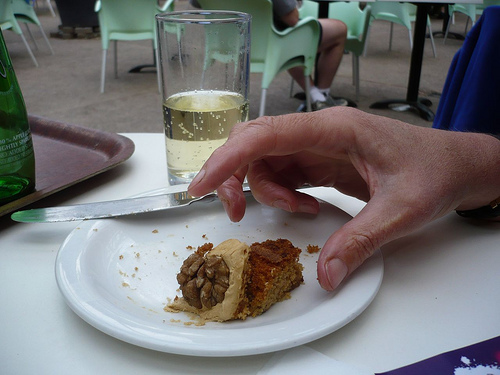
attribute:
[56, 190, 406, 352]
plate — white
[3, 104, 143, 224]
tray — brown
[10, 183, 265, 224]
knife — round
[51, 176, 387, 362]
plate — white, round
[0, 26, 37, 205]
bottle — green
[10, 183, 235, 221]
knife — white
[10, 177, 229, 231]
knife — round, white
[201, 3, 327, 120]
chair — light green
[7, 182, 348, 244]
knife — silver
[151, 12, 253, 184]
glass — filled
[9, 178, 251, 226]
knife — white